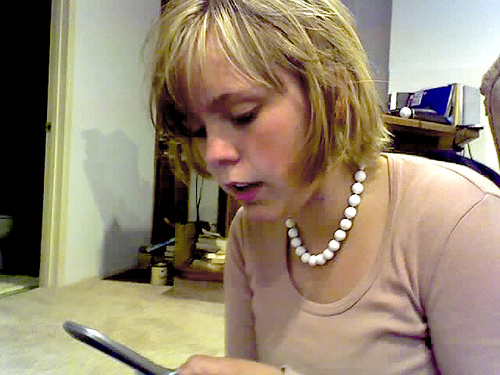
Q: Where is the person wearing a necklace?
A: Around their neck.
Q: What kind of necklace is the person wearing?
A: Pearls.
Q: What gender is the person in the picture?
A: Female.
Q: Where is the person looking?
A: At their phone.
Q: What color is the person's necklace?
A: White.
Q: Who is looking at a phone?
A: The girl.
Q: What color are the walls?
A: White.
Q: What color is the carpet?
A: Tan.